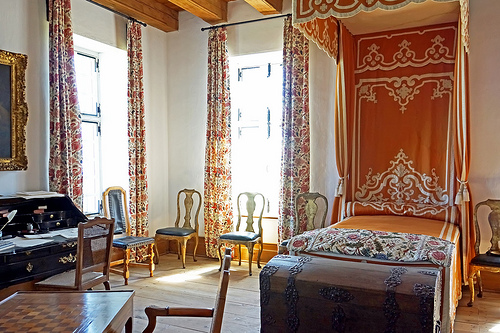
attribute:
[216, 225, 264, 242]
cushion — blue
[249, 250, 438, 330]
chest — Wooden 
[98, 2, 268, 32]
beams — wood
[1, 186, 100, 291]
desk — black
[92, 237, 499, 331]
floor — light , colored , wood 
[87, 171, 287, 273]
chairs — wood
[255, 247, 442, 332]
trunk — wooden 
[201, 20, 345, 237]
window — large 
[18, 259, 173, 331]
chess board — wood 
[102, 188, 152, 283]
chair — Wooden 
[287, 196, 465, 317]
bed — orange 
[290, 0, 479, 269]
canopy — white 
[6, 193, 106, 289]
desk — black 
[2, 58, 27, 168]
picture frame — gold 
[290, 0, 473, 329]
canopy bed — tall , canopy 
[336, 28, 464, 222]
curtains — open , bed 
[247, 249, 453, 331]
trunk — large, brown